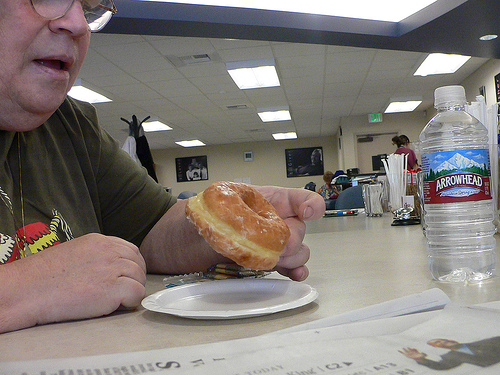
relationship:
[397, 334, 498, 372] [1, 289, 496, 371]
image printed on newspaper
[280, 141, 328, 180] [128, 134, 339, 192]
poster hanging on wall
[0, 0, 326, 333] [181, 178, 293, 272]
person holding doughnut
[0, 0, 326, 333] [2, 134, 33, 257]
person wearing necklace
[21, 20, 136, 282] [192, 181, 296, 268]
person holding donut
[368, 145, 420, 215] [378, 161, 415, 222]
straws in cup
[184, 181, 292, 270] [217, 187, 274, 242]
glazed doughnut has glaze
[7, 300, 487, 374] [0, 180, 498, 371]
newspaper on table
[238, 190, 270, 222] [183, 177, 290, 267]
hole in doughnut